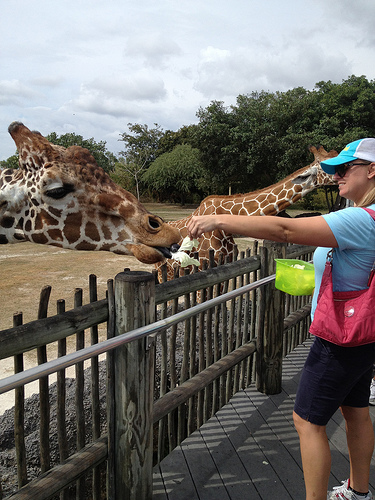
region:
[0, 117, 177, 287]
a woman petting a giraffe.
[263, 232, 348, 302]
a green object.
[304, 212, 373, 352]
a pink hand bag.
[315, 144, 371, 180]
a blue and white hat.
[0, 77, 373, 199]
a lush green forest of trees.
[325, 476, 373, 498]
a right foot shoe.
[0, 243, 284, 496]
a metal iron fence.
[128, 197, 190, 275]
the nose of a giraffe.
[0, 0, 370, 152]
a gray cloud of the sky.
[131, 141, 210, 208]
a large green bush.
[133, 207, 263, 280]
a friendly exchange of lettuce between woman+giraffe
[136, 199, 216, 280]
giraffe's nose & mouth are ~4x as big as woman's whole hand!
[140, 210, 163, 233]
giraffe has titanic nostril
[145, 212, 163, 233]
nostril is big, dark, deep like the sea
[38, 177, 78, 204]
giraffe has tremendous, though beautiful, dark eye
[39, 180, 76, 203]
eye has long black eyelashes, eyeliner-like rim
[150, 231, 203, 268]
black tongue against white lettuce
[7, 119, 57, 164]
giraffe has two reasonably short+stout horns w/ fuzzyfur tops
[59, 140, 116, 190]
giraffe has numerous bumpy bumps on large long forehead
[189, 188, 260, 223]
giraffe in middle distance has large crook in neck, as neck is bent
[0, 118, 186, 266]
the head of a giraffe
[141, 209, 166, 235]
the nose of a giraffe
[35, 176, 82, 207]
the eye of a giraffe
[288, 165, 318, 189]
the ear of a giraffe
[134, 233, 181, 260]
the mouth of a giraffe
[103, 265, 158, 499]
a brown wooden post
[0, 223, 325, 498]
a brown wooden fence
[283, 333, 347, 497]
the leg of a person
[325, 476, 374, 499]
a white shoe on the person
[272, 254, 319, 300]
a green plastic container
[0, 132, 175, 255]
this is a giraffes head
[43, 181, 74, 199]
this is an eye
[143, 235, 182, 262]
the giraffe is feeding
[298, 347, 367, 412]
she is wearing shorts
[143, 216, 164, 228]
the nose is big in size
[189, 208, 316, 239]
the hand is raised in front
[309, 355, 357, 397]
the short is black in color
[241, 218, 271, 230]
the hand is white in color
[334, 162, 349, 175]
the woman is wearing goggles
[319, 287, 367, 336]
the bag is pink in color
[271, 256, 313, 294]
bowl of giraffe food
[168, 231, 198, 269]
lettuce giraffe is eating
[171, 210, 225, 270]
hand of lady feeding animal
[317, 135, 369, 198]
head shot of lady feeding giraffe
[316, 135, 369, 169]
lady's hat she wearing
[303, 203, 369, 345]
pink bag being carried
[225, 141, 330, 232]
2nd giraffe being fed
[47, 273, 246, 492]
fence bordering animal and humans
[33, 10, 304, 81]
clouds in the sky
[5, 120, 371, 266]
lady feeding the giraffe